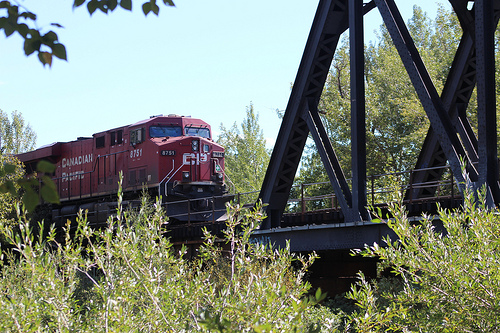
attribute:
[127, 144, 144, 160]
numbers — white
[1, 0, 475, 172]
sky — blue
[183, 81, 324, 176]
clouds — white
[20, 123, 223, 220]
train — metal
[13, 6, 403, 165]
sky — blue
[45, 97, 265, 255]
train — red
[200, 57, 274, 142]
clouds — white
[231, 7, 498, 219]
crossbeams — metal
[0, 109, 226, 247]
train — crossing, red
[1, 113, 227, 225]
train — red, bringing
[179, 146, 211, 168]
cp — white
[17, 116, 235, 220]
engine — red 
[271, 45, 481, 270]
bridge — brown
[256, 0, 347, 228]
beam — steel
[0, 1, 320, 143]
sky — blue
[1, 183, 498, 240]
railing — black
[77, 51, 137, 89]
clouds — white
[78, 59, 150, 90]
clouds — white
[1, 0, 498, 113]
sky — blue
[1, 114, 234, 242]
train — red